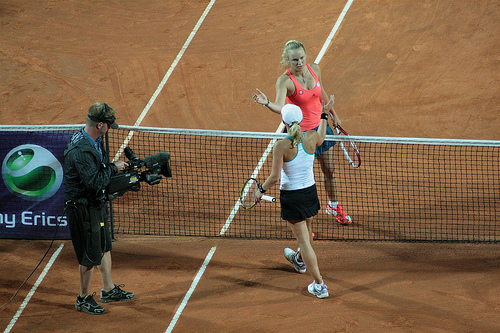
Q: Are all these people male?
A: No, they are both male and female.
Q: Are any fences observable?
A: No, there are no fences.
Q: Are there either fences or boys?
A: No, there are no fences or boys.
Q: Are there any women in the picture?
A: Yes, there is a woman.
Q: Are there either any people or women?
A: Yes, there is a woman.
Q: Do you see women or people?
A: Yes, there is a woman.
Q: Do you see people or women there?
A: Yes, there is a woman.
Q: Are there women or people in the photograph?
A: Yes, there is a woman.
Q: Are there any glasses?
A: No, there are no glasses.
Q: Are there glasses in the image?
A: No, there are no glasses.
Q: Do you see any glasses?
A: No, there are no glasses.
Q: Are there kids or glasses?
A: No, there are no glasses or kids.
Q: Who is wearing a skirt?
A: The woman is wearing a skirt.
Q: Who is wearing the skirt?
A: The woman is wearing a skirt.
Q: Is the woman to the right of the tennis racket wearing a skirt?
A: Yes, the woman is wearing a skirt.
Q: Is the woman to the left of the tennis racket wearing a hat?
A: No, the woman is wearing a skirt.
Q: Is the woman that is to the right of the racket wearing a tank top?
A: Yes, the woman is wearing a tank top.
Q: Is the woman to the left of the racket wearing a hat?
A: No, the woman is wearing a tank top.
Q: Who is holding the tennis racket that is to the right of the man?
A: The woman is holding the racket.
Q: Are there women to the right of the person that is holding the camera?
A: Yes, there is a woman to the right of the man.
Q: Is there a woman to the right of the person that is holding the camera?
A: Yes, there is a woman to the right of the man.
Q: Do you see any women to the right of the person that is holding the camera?
A: Yes, there is a woman to the right of the man.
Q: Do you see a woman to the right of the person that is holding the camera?
A: Yes, there is a woman to the right of the man.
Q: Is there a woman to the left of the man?
A: No, the woman is to the right of the man.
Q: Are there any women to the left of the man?
A: No, the woman is to the right of the man.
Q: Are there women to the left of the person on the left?
A: No, the woman is to the right of the man.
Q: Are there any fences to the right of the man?
A: No, there is a woman to the right of the man.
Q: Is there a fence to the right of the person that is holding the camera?
A: No, there is a woman to the right of the man.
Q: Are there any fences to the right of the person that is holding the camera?
A: No, there is a woman to the right of the man.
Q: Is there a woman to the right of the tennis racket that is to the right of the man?
A: Yes, there is a woman to the right of the racket.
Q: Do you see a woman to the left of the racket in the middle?
A: No, the woman is to the right of the tennis racket.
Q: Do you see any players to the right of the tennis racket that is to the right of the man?
A: No, there is a woman to the right of the tennis racket.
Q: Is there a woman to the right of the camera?
A: Yes, there is a woman to the right of the camera.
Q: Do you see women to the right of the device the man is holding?
A: Yes, there is a woman to the right of the camera.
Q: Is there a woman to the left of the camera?
A: No, the woman is to the right of the camera.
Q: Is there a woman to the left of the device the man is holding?
A: No, the woman is to the right of the camera.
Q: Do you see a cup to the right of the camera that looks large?
A: No, there is a woman to the right of the camera.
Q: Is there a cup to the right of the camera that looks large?
A: No, there is a woman to the right of the camera.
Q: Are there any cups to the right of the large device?
A: No, there is a woman to the right of the camera.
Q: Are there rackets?
A: Yes, there is a racket.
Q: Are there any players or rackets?
A: Yes, there is a racket.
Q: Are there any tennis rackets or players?
A: Yes, there is a tennis racket.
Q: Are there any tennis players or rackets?
A: Yes, there is a tennis racket.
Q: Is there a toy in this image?
A: No, there are no toys.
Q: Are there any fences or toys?
A: No, there are no toys or fences.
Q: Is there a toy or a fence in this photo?
A: No, there are no toys or fences.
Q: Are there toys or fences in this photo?
A: No, there are no toys or fences.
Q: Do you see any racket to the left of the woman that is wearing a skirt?
A: Yes, there is a racket to the left of the woman.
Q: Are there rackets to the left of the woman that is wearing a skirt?
A: Yes, there is a racket to the left of the woman.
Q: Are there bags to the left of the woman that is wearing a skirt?
A: No, there is a racket to the left of the woman.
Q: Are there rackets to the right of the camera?
A: Yes, there is a racket to the right of the camera.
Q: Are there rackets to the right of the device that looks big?
A: Yes, there is a racket to the right of the camera.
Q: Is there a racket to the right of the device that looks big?
A: Yes, there is a racket to the right of the camera.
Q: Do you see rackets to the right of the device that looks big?
A: Yes, there is a racket to the right of the camera.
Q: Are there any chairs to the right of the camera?
A: No, there is a racket to the right of the camera.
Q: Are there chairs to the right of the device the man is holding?
A: No, there is a racket to the right of the camera.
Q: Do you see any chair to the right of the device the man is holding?
A: No, there is a racket to the right of the camera.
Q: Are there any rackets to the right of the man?
A: Yes, there is a racket to the right of the man.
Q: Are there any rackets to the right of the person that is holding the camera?
A: Yes, there is a racket to the right of the man.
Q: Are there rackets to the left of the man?
A: No, the racket is to the right of the man.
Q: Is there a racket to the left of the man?
A: No, the racket is to the right of the man.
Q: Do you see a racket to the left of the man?
A: No, the racket is to the right of the man.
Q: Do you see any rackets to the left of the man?
A: No, the racket is to the right of the man.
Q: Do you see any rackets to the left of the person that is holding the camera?
A: No, the racket is to the right of the man.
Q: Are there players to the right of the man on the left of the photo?
A: No, there is a racket to the right of the man.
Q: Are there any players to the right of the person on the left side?
A: No, there is a racket to the right of the man.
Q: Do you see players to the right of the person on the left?
A: No, there is a racket to the right of the man.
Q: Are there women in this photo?
A: Yes, there is a woman.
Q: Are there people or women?
A: Yes, there is a woman.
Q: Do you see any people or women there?
A: Yes, there is a woman.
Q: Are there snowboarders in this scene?
A: No, there are no snowboarders.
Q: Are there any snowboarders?
A: No, there are no snowboarders.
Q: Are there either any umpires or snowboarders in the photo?
A: No, there are no snowboarders or umpires.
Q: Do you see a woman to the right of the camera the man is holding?
A: Yes, there is a woman to the right of the camera.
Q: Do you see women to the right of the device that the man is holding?
A: Yes, there is a woman to the right of the camera.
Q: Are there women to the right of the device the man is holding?
A: Yes, there is a woman to the right of the camera.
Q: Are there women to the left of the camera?
A: No, the woman is to the right of the camera.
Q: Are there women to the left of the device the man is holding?
A: No, the woman is to the right of the camera.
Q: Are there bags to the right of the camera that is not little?
A: No, there is a woman to the right of the camera.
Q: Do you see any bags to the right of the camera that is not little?
A: No, there is a woman to the right of the camera.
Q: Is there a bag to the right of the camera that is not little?
A: No, there is a woman to the right of the camera.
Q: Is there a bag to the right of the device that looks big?
A: No, there is a woman to the right of the camera.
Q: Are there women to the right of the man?
A: Yes, there is a woman to the right of the man.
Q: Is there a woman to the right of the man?
A: Yes, there is a woman to the right of the man.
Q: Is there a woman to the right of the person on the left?
A: Yes, there is a woman to the right of the man.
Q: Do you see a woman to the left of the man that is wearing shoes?
A: No, the woman is to the right of the man.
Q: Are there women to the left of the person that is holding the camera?
A: No, the woman is to the right of the man.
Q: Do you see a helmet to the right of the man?
A: No, there is a woman to the right of the man.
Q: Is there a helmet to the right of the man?
A: No, there is a woman to the right of the man.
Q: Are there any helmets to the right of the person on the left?
A: No, there is a woman to the right of the man.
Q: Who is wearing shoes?
A: The woman is wearing shoes.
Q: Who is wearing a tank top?
A: The woman is wearing a tank top.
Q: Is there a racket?
A: Yes, there is a racket.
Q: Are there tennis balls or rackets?
A: Yes, there is a racket.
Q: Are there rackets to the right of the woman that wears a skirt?
A: Yes, there is a racket to the right of the woman.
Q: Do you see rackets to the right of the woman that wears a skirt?
A: Yes, there is a racket to the right of the woman.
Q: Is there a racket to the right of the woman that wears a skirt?
A: Yes, there is a racket to the right of the woman.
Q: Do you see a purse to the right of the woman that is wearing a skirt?
A: No, there is a racket to the right of the woman.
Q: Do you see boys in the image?
A: No, there are no boys.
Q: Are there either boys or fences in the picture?
A: No, there are no boys or fences.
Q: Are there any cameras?
A: Yes, there is a camera.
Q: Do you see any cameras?
A: Yes, there is a camera.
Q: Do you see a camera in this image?
A: Yes, there is a camera.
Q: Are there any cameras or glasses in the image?
A: Yes, there is a camera.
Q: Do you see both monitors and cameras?
A: No, there is a camera but no monitors.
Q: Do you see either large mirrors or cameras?
A: Yes, there is a large camera.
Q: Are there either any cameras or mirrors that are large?
A: Yes, the camera is large.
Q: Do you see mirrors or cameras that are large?
A: Yes, the camera is large.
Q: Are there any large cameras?
A: Yes, there is a large camera.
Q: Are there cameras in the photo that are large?
A: Yes, there is a camera that is large.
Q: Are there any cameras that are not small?
A: Yes, there is a large camera.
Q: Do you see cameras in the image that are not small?
A: Yes, there is a large camera.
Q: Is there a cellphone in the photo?
A: No, there are no cell phones.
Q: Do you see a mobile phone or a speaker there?
A: No, there are no cell phones or speakers.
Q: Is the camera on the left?
A: Yes, the camera is on the left of the image.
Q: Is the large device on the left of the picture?
A: Yes, the camera is on the left of the image.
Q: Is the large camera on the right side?
A: No, the camera is on the left of the image.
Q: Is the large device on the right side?
A: No, the camera is on the left of the image.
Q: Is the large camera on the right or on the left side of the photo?
A: The camera is on the left of the image.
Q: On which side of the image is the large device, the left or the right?
A: The camera is on the left of the image.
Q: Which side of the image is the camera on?
A: The camera is on the left of the image.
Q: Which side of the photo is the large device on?
A: The camera is on the left of the image.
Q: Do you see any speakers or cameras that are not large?
A: No, there is a camera but it is large.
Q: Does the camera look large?
A: Yes, the camera is large.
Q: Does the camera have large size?
A: Yes, the camera is large.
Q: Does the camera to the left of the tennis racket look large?
A: Yes, the camera is large.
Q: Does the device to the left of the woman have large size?
A: Yes, the camera is large.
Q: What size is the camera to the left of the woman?
A: The camera is large.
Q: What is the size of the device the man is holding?
A: The camera is large.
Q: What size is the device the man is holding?
A: The camera is large.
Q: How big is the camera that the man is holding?
A: The camera is large.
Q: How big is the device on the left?
A: The camera is large.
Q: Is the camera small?
A: No, the camera is large.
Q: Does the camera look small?
A: No, the camera is large.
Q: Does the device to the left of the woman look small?
A: No, the camera is large.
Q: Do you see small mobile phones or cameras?
A: No, there is a camera but it is large.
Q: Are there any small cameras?
A: No, there is a camera but it is large.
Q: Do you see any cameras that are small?
A: No, there is a camera but it is large.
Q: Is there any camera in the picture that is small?
A: No, there is a camera but it is large.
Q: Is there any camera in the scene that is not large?
A: No, there is a camera but it is large.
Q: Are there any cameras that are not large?
A: No, there is a camera but it is large.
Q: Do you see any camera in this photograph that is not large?
A: No, there is a camera but it is large.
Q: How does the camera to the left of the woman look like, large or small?
A: The camera is large.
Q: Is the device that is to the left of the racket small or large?
A: The camera is large.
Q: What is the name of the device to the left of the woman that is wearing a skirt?
A: The device is a camera.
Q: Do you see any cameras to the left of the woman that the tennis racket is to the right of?
A: Yes, there is a camera to the left of the woman.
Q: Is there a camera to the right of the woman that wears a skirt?
A: No, the camera is to the left of the woman.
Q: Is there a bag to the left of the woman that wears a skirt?
A: No, there is a camera to the left of the woman.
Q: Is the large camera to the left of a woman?
A: Yes, the camera is to the left of a woman.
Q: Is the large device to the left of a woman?
A: Yes, the camera is to the left of a woman.